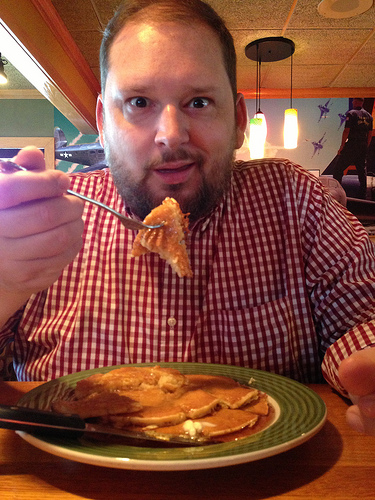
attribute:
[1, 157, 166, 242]
fork — silver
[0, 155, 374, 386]
shirt — checked, red, white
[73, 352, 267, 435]
pancakes — drowned, cut, piled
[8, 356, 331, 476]
plate — green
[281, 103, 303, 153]
light — glowing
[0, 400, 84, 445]
handle — black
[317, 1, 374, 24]
speaker — white